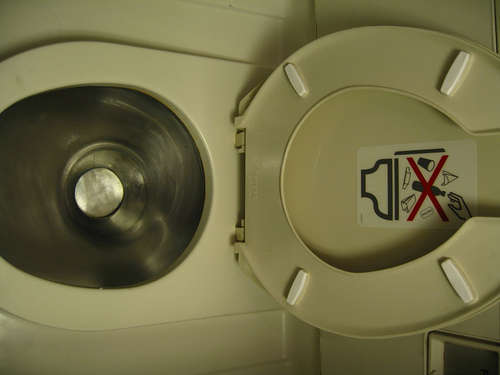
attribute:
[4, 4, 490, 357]
toilet — white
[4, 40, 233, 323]
seat — white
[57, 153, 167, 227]
toilet bowl — wider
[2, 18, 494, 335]
toilet — clean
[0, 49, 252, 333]
bowl — metal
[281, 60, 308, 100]
bumper — white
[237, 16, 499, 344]
lid — white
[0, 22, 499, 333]
toilet seat — white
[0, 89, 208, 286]
toilet inside — stainless steel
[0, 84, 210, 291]
toilet bowl — silver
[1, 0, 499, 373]
room — well lit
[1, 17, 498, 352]
seat — white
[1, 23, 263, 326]
toilet base — vanilla colored